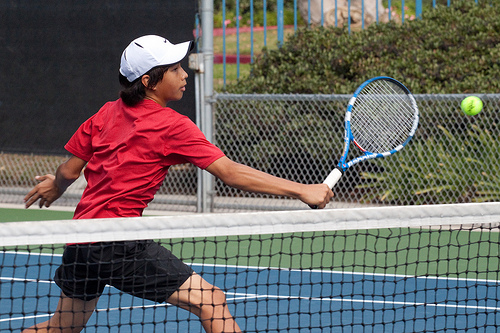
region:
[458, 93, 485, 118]
a tennis ball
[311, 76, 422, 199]
a blue and white tennis racket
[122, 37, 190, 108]
a boy wearing a white cap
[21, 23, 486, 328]
a young man playing tennis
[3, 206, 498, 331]
the net on a tennis court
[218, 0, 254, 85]
blue metal posts on a fence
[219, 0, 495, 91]
green bushes in front of a fence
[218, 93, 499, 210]
a chain link fence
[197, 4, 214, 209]
a metal post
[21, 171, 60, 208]
the left hand of a boy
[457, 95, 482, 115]
the green tennis ball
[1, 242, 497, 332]
the black tennis net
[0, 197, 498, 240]
the white edge on top of the net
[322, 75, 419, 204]
the white and blue tennis racquet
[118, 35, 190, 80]
the white baseball cap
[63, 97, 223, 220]
the red short sleeved shirt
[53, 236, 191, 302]
the black shorts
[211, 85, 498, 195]
the silver metal fence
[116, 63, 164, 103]
the boy's black hair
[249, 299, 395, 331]
the blue part of the tennis court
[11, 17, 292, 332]
Young boy playing tennis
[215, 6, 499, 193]
Bushes next to the tennis court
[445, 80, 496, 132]
Tennis ball in motion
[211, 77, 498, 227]
Chain link fence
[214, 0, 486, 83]
Blue metal fence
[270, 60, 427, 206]
Blue and white tennis racket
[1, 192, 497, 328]
Tennis net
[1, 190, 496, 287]
Green out of bounds area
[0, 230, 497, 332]
Blue tennis court area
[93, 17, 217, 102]
White cap on boy's head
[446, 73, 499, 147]
a yellow tennis ball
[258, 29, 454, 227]
a tennis racket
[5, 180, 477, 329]
a white tennis net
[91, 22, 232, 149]
a person wearing a white hat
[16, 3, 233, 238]
a person wearing a red shirt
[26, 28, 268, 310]
a person wearing black shorts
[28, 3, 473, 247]
a person playing tennis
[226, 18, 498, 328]
green bushes next to a tennis court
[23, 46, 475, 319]
a tennis court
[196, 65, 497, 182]
a metal fence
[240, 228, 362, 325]
the net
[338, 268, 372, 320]
the net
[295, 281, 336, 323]
the net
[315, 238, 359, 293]
the net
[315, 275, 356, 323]
the net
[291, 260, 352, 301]
the net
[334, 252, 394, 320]
the net